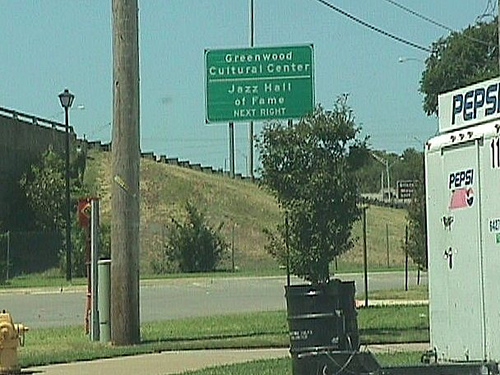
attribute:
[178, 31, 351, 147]
road sign — green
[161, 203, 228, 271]
bush — tall, green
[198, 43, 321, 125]
sign — green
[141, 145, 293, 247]
highway ramp — highway 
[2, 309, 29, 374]
fire hydrant — yellow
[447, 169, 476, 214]
sign — Pepsi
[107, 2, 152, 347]
post — tall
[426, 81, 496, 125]
signage — pepsi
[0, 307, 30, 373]
fire hydrant — yellow fire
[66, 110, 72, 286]
post — tall, metal